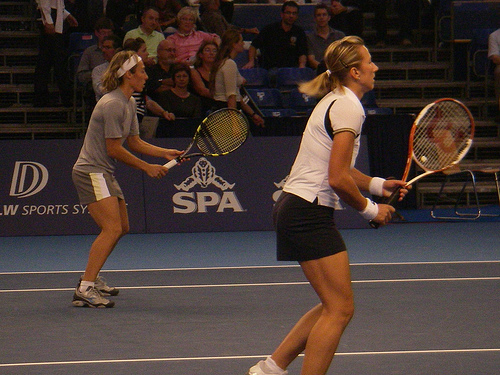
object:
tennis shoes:
[89, 277, 120, 297]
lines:
[0, 259, 500, 292]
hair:
[101, 51, 139, 91]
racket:
[163, 108, 250, 171]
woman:
[245, 37, 413, 375]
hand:
[164, 148, 191, 166]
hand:
[242, 62, 255, 70]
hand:
[200, 88, 211, 97]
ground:
[413, 172, 458, 215]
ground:
[435, 148, 445, 168]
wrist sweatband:
[368, 176, 385, 197]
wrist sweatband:
[359, 198, 379, 221]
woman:
[166, 7, 221, 67]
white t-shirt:
[281, 85, 366, 210]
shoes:
[72, 283, 116, 308]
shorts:
[274, 191, 348, 262]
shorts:
[70, 168, 125, 206]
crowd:
[43, 1, 343, 136]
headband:
[113, 54, 142, 79]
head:
[111, 50, 149, 92]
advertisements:
[172, 157, 247, 214]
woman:
[70, 52, 191, 311]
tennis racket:
[159, 103, 254, 170]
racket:
[369, 98, 475, 230]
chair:
[430, 128, 499, 220]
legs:
[429, 172, 499, 220]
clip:
[339, 58, 349, 68]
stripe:
[89, 170, 112, 201]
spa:
[172, 191, 245, 214]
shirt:
[166, 30, 220, 64]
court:
[0, 207, 500, 375]